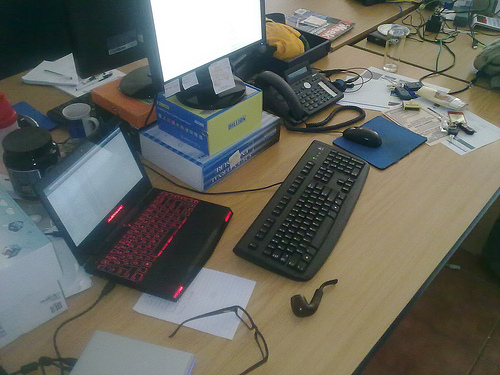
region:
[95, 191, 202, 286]
keys on a keyboard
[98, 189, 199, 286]
keys that are lit up with red lights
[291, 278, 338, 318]
a pipe on a table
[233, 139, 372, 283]
a keyboard on a table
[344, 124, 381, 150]
a black computer mouse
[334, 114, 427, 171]
a blue mouse pad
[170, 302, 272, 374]
a pair of glasses on a table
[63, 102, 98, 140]
a blue and white coffee mug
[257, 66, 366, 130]
a mult line telephone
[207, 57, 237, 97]
a white postit note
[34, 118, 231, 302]
black laptop computer with pink accents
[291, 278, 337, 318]
dark brown tobacco smoking pipe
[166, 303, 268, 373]
black glasses with clear lenses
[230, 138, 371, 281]
black keyboard with white letters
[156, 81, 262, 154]
yellow and blue box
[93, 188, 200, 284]
black and pink laptop keyboard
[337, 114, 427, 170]
black mouse on blue mousepad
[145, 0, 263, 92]
black illuminated LCD computer monitor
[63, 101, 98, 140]
empty blue and white coffee mug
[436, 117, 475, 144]
car keys with electronic entry FOB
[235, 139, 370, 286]
a keyboard is black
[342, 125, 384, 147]
computer mouse is black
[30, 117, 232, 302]
a black and red keyboard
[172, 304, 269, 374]
a pair of glasses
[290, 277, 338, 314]
a brown wooden pipe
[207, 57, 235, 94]
piece of paper on a screen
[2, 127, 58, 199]
a black lid on a jar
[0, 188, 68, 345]
two reams of paper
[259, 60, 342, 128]
a black office phone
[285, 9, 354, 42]
a magazine on a table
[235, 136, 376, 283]
a keyboard on a desk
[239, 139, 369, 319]
a keyboard and pipe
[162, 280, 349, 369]
a pipe and pair of glasses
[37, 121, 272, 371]
an open laptop and glasses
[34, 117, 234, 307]
an open laptop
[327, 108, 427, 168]
a mouse and mouse pad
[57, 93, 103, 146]
a coffee cup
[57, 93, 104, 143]
a blue and white coffee cup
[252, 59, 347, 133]
a telephone on a desk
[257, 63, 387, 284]
a telephone, keyboard and mouse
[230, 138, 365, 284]
a keyboard on a desk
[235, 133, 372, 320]
a keyboard and a pipe on a desk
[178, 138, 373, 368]
a keyboard, pipe and glasses on a desk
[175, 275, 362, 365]
a pipe and glasses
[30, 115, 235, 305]
an open laptop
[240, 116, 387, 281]
a keyboard and mouse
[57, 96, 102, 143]
an empty coffee cup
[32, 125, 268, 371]
a laptop and pair of glasses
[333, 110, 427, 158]
a mouse and mouse pad